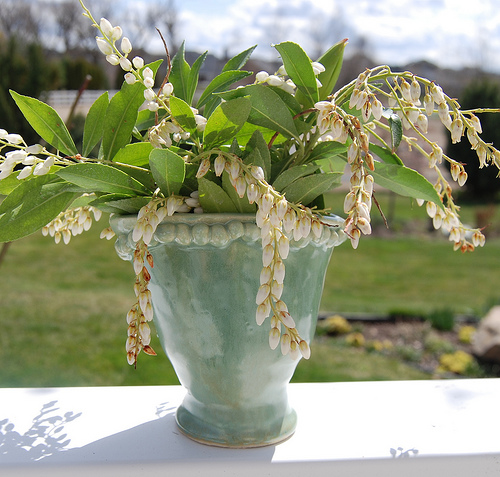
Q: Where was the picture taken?
A: It was taken at the yard.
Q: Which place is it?
A: It is a yard.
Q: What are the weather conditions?
A: It is cloudy.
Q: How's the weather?
A: It is cloudy.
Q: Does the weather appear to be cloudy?
A: Yes, it is cloudy.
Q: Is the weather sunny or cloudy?
A: It is cloudy.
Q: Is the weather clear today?
A: No, it is cloudy.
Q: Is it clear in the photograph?
A: No, it is cloudy.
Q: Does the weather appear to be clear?
A: No, it is cloudy.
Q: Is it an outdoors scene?
A: Yes, it is outdoors.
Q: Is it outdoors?
A: Yes, it is outdoors.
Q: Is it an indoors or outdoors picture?
A: It is outdoors.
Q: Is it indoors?
A: No, it is outdoors.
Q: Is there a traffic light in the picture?
A: No, there are no traffic lights.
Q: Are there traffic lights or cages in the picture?
A: No, there are no traffic lights or cages.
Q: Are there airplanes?
A: No, there are no airplanes.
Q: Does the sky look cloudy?
A: Yes, the sky is cloudy.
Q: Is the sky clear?
A: No, the sky is cloudy.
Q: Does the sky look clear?
A: No, the sky is cloudy.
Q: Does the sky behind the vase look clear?
A: No, the sky is cloudy.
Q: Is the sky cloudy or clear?
A: The sky is cloudy.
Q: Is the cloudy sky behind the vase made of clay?
A: Yes, the sky is behind the vase.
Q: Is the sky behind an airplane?
A: No, the sky is behind the vase.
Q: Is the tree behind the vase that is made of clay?
A: Yes, the tree is behind the vase.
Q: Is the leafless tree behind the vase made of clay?
A: Yes, the tree is behind the vase.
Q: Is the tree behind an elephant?
A: No, the tree is behind the vase.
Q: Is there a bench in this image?
A: No, there are no benches.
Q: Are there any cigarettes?
A: No, there are no cigarettes.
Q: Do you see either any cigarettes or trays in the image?
A: No, there are no cigarettes or trays.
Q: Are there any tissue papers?
A: No, there are no tissue papers.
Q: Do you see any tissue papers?
A: No, there are no tissue papers.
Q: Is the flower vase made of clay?
A: Yes, the vase is made of clay.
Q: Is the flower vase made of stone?
A: No, the vase is made of clay.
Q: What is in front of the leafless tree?
A: The vase is in front of the tree.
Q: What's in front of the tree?
A: The vase is in front of the tree.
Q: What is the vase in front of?
A: The vase is in front of the tree.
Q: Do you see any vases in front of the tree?
A: Yes, there is a vase in front of the tree.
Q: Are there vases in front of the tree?
A: Yes, there is a vase in front of the tree.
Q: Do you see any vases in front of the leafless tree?
A: Yes, there is a vase in front of the tree.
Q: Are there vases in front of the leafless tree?
A: Yes, there is a vase in front of the tree.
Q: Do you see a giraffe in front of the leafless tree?
A: No, there is a vase in front of the tree.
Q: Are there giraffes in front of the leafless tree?
A: No, there is a vase in front of the tree.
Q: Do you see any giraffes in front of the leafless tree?
A: No, there is a vase in front of the tree.